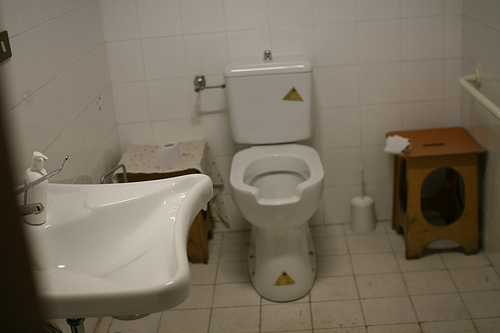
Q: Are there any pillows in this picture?
A: No, there are no pillows.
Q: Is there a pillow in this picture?
A: No, there are no pillows.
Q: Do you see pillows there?
A: No, there are no pillows.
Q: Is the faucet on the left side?
A: Yes, the faucet is on the left of the image.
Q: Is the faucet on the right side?
A: No, the faucet is on the left of the image.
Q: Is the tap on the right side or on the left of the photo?
A: The tap is on the left of the image.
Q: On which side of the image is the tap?
A: The tap is on the left of the image.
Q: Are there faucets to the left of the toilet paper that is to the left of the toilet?
A: Yes, there is a faucet to the left of the toilet paper.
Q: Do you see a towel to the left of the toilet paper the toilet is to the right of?
A: No, there is a faucet to the left of the toilet paper.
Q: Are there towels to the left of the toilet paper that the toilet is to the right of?
A: No, there is a faucet to the left of the toilet paper.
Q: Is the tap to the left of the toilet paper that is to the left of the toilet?
A: Yes, the tap is to the left of the toilet paper.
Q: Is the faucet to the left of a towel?
A: No, the faucet is to the left of the toilet paper.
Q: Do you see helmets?
A: No, there are no helmets.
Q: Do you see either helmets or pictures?
A: No, there are no helmets or pictures.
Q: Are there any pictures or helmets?
A: No, there are no helmets or pictures.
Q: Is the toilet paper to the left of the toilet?
A: Yes, the toilet paper is to the left of the toilet.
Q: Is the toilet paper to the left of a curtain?
A: No, the toilet paper is to the left of the toilet.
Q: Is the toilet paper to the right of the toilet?
A: No, the toilet paper is to the left of the toilet.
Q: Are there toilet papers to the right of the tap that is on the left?
A: Yes, there is a toilet paper to the right of the tap.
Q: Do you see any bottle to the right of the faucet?
A: No, there is a toilet paper to the right of the faucet.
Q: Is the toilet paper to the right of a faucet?
A: Yes, the toilet paper is to the right of a faucet.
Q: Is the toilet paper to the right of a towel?
A: No, the toilet paper is to the right of a faucet.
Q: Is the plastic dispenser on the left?
A: Yes, the dispenser is on the left of the image.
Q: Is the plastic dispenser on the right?
A: No, the dispenser is on the left of the image.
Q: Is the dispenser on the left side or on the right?
A: The dispenser is on the left of the image.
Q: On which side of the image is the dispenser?
A: The dispenser is on the left of the image.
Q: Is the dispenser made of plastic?
A: Yes, the dispenser is made of plastic.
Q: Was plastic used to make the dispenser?
A: Yes, the dispenser is made of plastic.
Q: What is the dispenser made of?
A: The dispenser is made of plastic.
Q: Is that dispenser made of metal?
A: No, the dispenser is made of plastic.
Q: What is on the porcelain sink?
A: The dispenser is on the sink.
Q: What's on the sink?
A: The dispenser is on the sink.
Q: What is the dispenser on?
A: The dispenser is on the sink.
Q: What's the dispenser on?
A: The dispenser is on the sink.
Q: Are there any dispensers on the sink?
A: Yes, there is a dispenser on the sink.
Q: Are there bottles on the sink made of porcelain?
A: No, there is a dispenser on the sink.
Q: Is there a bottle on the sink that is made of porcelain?
A: No, there is a dispenser on the sink.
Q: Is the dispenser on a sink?
A: Yes, the dispenser is on a sink.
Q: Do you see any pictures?
A: No, there are no pictures.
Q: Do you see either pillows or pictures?
A: No, there are no pictures or pillows.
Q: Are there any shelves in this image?
A: No, there are no shelves.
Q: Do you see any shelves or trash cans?
A: No, there are no shelves or trash cans.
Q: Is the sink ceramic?
A: Yes, the sink is ceramic.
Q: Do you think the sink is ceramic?
A: Yes, the sink is ceramic.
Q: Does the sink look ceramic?
A: Yes, the sink is ceramic.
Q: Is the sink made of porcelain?
A: Yes, the sink is made of porcelain.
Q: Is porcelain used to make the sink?
A: Yes, the sink is made of porcelain.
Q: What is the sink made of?
A: The sink is made of porcelain.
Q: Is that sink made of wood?
A: No, the sink is made of porcelain.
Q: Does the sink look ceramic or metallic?
A: The sink is ceramic.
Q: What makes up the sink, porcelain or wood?
A: The sink is made of porcelain.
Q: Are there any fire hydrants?
A: No, there are no fire hydrants.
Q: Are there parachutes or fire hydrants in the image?
A: No, there are no fire hydrants or parachutes.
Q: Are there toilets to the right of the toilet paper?
A: Yes, there is a toilet to the right of the toilet paper.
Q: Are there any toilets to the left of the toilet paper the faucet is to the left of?
A: No, the toilet is to the right of the toilet paper.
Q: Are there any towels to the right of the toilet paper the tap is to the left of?
A: No, there is a toilet to the right of the toilet paper.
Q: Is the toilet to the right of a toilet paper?
A: Yes, the toilet is to the right of a toilet paper.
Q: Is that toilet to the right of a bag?
A: No, the toilet is to the right of a toilet paper.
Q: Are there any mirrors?
A: No, there are no mirrors.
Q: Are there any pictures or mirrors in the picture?
A: No, there are no mirrors or pictures.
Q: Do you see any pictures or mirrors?
A: No, there are no mirrors or pictures.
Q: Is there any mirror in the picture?
A: No, there are no mirrors.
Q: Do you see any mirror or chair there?
A: No, there are no mirrors or chairs.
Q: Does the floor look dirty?
A: Yes, the floor is dirty.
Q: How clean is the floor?
A: The floor is dirty.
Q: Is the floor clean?
A: No, the floor is dirty.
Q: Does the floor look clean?
A: No, the floor is dirty.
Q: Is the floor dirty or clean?
A: The floor is dirty.